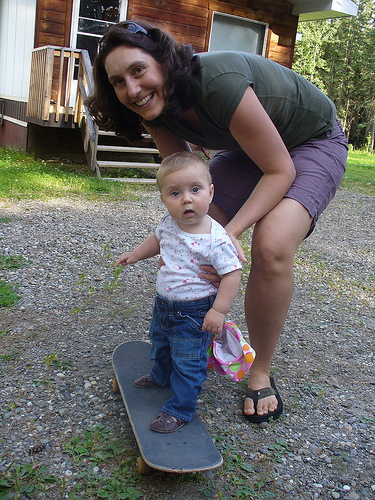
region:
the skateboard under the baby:
[111, 339, 222, 474]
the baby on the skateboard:
[115, 151, 240, 432]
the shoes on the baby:
[133, 371, 186, 431]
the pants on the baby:
[148, 290, 216, 421]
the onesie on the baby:
[155, 210, 241, 299]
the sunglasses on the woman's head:
[96, 21, 155, 40]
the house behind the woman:
[0, 0, 360, 182]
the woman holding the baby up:
[83, 20, 348, 422]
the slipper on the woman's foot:
[244, 376, 283, 422]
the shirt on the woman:
[140, 48, 335, 156]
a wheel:
[129, 455, 149, 473]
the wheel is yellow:
[132, 454, 146, 473]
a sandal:
[247, 385, 274, 414]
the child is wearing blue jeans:
[174, 346, 197, 405]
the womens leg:
[248, 250, 288, 337]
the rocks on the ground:
[19, 386, 70, 420]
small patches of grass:
[91, 472, 136, 496]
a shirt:
[167, 245, 197, 276]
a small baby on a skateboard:
[98, 167, 234, 471]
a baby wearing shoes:
[128, 146, 234, 447]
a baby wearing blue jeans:
[110, 157, 231, 423]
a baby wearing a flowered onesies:
[117, 154, 238, 306]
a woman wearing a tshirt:
[83, 16, 365, 158]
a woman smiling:
[101, 36, 183, 132]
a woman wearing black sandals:
[97, 22, 354, 497]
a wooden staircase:
[24, 42, 180, 181]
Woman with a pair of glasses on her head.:
[91, 16, 352, 426]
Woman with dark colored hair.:
[84, 20, 347, 423]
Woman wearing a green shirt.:
[87, 20, 351, 427]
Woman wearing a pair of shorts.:
[86, 21, 347, 427]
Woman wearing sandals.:
[83, 18, 347, 426]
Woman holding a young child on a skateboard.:
[88, 20, 347, 420]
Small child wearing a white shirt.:
[117, 151, 243, 436]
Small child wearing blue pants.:
[114, 152, 240, 438]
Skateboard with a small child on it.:
[108, 337, 232, 479]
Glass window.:
[203, 8, 270, 57]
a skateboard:
[150, 433, 215, 457]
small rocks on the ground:
[306, 399, 357, 449]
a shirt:
[164, 245, 194, 284]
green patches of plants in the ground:
[94, 478, 132, 497]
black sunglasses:
[121, 20, 142, 37]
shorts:
[297, 152, 338, 185]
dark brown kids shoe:
[154, 412, 180, 430]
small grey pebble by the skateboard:
[272, 471, 278, 479]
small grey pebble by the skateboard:
[285, 482, 295, 494]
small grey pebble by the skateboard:
[308, 437, 318, 447]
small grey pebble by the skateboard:
[331, 448, 340, 455]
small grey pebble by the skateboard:
[347, 444, 355, 454]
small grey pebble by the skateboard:
[91, 462, 96, 467]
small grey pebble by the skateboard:
[227, 411, 235, 423]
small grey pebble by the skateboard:
[206, 385, 215, 390]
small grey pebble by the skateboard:
[233, 405, 245, 418]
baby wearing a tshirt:
[137, 146, 237, 419]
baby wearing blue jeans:
[139, 155, 227, 430]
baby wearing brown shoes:
[130, 151, 236, 448]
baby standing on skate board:
[153, 140, 220, 428]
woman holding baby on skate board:
[135, 22, 347, 437]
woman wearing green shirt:
[90, 17, 351, 143]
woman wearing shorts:
[86, 19, 360, 152]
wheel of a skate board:
[114, 454, 148, 474]